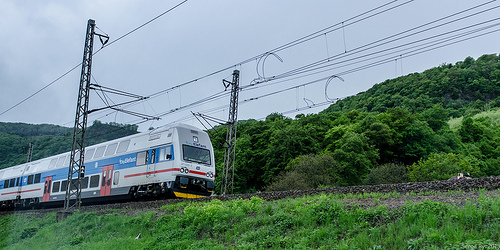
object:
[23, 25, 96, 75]
clouds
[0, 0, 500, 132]
sky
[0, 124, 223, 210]
train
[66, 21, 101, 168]
post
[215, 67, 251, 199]
towers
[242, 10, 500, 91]
wires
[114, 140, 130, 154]
windows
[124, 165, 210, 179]
stripe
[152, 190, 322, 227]
hill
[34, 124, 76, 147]
slope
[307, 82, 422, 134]
vegetation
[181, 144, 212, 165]
windshield